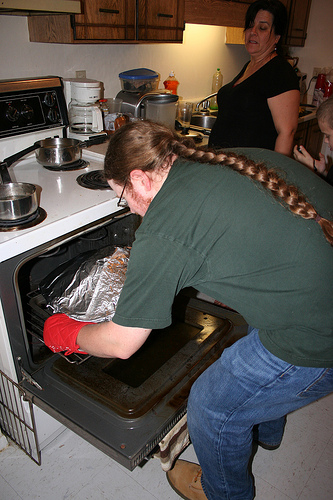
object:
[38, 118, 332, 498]
man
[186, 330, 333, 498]
blue jeans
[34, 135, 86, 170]
pot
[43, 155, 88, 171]
burner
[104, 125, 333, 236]
man's hair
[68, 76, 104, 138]
coffee maker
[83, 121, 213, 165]
counter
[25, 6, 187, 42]
cabinets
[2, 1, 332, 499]
kitchen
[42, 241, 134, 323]
aluminum foil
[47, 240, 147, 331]
food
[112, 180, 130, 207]
glasses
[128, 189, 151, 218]
beard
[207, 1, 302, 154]
woman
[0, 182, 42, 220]
saucepan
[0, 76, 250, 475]
stove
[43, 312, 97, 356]
oven mitt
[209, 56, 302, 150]
woman's shirt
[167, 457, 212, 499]
boots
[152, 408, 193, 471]
towel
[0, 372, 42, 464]
rack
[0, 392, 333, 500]
floor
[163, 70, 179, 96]
dish soap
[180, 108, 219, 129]
sink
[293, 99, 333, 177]
child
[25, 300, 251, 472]
oven door